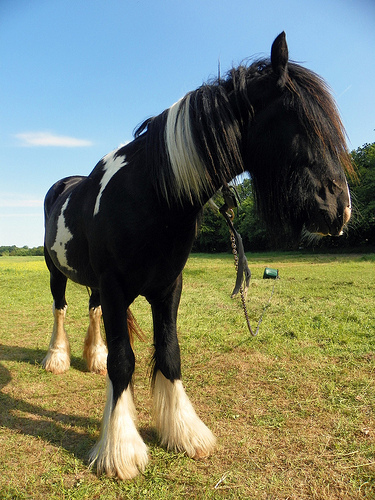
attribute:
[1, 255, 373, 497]
grass — green 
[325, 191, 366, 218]
nose — pink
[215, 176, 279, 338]
chain — metal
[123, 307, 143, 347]
tail — brown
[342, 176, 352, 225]
nose patch — white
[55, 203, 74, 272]
spots — white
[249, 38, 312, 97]
ear — black 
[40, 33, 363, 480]
tail horse — black 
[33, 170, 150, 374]
tail horse — black 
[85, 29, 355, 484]
tail horse — black 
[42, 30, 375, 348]
tail horse — black 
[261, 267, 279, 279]
bucket — green 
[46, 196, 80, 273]
patch — white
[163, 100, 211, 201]
hair — white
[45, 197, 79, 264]
spot — white 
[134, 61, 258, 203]
mane — white 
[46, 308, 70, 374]
hoof — white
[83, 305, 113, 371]
hoof — white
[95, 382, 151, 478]
hoof — white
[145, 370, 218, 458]
hoof — white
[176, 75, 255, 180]
mane — black 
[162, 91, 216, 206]
mane — white 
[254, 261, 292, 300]
bucket — feed, green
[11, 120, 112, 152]
cloud — white 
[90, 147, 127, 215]
spot — white 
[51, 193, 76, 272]
spot — white 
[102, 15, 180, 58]
blue sky — blue 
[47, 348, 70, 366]
white hair — long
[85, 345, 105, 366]
white hair — long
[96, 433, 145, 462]
white hair — long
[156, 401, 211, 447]
white hair — long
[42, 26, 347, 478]
horse — black, Clydesdale , tall